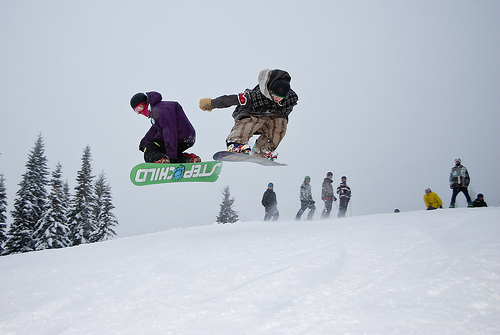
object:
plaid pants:
[226, 112, 288, 152]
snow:
[0, 128, 500, 335]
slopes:
[1, 201, 500, 335]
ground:
[0, 207, 500, 335]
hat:
[272, 79, 291, 99]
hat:
[129, 92, 147, 113]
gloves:
[198, 97, 212, 111]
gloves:
[138, 138, 150, 152]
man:
[449, 157, 476, 209]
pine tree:
[215, 184, 239, 224]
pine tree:
[66, 142, 99, 245]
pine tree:
[2, 130, 56, 255]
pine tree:
[32, 162, 74, 251]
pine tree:
[91, 171, 119, 243]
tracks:
[147, 220, 391, 335]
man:
[261, 182, 280, 222]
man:
[292, 175, 316, 222]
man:
[319, 172, 338, 219]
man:
[336, 175, 351, 218]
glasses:
[135, 104, 148, 115]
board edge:
[173, 180, 198, 184]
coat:
[424, 190, 443, 209]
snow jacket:
[423, 190, 443, 209]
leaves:
[0, 131, 117, 255]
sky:
[0, 0, 500, 237]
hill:
[0, 205, 500, 335]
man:
[129, 90, 203, 166]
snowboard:
[129, 160, 223, 187]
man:
[198, 67, 301, 161]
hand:
[199, 98, 213, 113]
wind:
[0, 0, 500, 211]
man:
[423, 187, 443, 210]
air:
[0, 0, 500, 243]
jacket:
[139, 90, 196, 160]